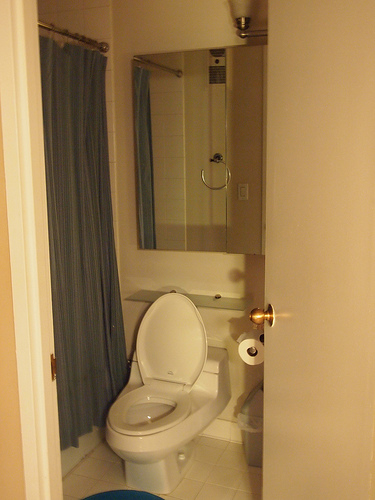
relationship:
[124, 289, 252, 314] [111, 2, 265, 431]
shelf on wall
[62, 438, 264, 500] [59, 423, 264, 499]
tile on floor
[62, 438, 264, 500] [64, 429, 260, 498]
tile on floor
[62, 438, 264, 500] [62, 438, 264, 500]
tile on tile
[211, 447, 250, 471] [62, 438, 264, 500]
tile on tile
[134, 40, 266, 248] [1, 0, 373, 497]
mirror in bathroom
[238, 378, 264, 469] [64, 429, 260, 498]
garbage can on floor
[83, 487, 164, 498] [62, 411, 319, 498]
bath mat lying on floor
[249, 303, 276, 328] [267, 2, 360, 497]
doorknob mounted on door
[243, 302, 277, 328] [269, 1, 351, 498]
doorknob mounted on door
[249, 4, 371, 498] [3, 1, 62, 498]
door mounted on bathroom frame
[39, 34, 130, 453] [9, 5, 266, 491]
shower curtain hanging in bathroom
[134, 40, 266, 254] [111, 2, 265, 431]
mirror hanging on wall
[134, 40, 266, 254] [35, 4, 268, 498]
mirror hanging in bathroom